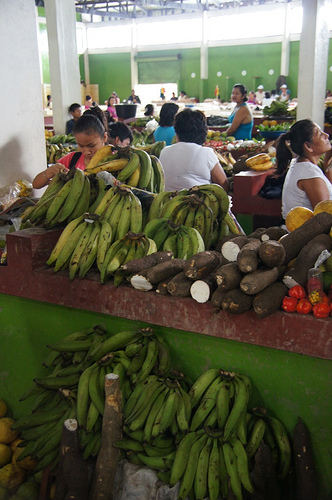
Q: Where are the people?
A: In a market.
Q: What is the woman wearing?
A: White shirt.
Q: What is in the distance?
A: A green wall.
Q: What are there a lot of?
A: Green bananas.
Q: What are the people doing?
A: Sitting.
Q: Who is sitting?
A: The people.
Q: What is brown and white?
A: Some of the food.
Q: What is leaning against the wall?
A: Green plantains.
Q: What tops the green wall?
A: Red brick.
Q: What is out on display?
A: Bananas.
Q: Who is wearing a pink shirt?
A: A woman.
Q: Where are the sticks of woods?
A: On the ground.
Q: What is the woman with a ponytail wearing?
A: A white shirt.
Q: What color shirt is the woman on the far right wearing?
A: White.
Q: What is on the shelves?
A: Produce.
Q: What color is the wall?
A: Green.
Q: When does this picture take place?
A: Daytime.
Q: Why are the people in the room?
A: Shopping.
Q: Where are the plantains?
A: On the shelves.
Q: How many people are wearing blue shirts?
A: Two.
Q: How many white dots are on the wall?
A: Four.